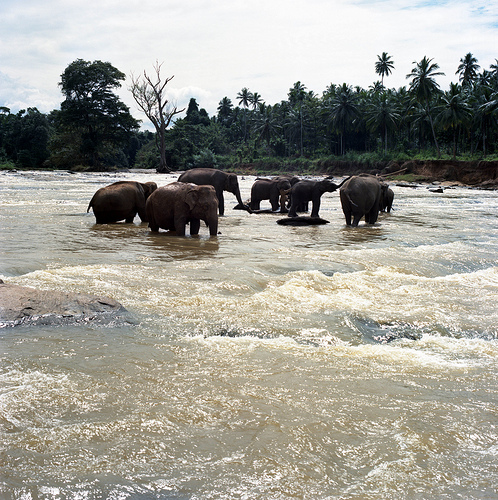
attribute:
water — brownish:
[57, 254, 471, 370]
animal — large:
[253, 169, 413, 230]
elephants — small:
[84, 162, 398, 239]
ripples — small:
[111, 416, 172, 431]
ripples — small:
[0, 368, 102, 429]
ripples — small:
[392, 431, 438, 453]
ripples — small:
[46, 413, 169, 439]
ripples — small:
[191, 333, 300, 350]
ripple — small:
[48, 416, 154, 498]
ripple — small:
[127, 444, 257, 488]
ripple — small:
[230, 433, 326, 497]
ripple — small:
[356, 415, 418, 498]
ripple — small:
[4, 360, 98, 415]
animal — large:
[338, 169, 395, 226]